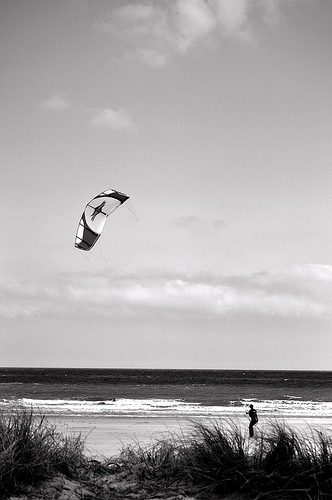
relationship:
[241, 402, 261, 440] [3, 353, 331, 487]
man on beach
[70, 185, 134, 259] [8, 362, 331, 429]
kiteboarder heading out to sea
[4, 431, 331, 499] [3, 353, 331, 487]
plants are above beach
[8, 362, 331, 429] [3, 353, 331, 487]
ocean meeting beach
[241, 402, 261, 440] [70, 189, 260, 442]
man going kitesurfing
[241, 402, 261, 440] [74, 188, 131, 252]
silhouette flying a kiteboarder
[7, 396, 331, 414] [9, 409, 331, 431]
waves are lapping shore line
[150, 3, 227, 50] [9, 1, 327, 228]
cloud in sky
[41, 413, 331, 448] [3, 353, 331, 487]
sand on beach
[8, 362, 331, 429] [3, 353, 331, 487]
water in ocean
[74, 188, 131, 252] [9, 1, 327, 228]
kiteboarder in sky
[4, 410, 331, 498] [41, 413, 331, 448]
grass in sand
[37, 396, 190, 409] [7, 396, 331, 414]
caps are on top of waves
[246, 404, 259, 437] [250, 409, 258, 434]
man wearing black